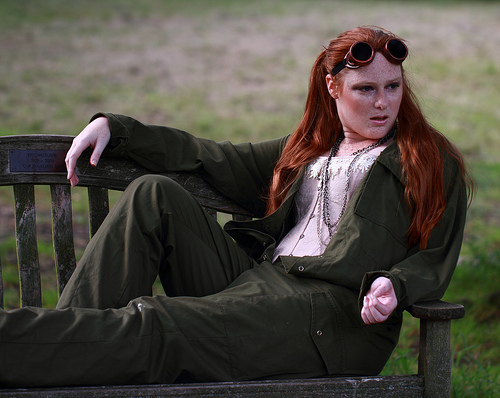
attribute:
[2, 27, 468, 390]
woman — sitting, posing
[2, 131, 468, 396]
bench — wooden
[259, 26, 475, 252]
hair — red, long, stylish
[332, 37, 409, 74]
goggles — copper, black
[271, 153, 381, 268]
top — white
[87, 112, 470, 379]
jacket — green